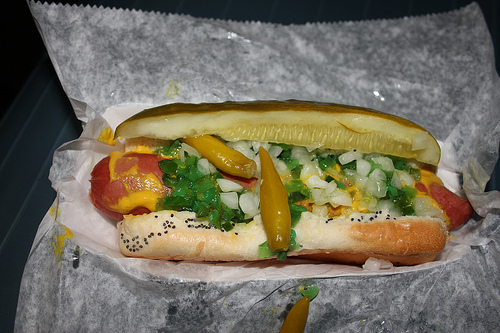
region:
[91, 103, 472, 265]
a hot dog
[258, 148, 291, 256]
small pickles in a hot dog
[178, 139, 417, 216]
chopped white onions in a hot dog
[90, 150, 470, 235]
a hot dog wiener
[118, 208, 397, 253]
poppy seeds on a hot dog bun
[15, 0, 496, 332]
a white paper wrapper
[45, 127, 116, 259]
mustard on a white paper wrapper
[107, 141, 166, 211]
mustard on the tip of a wiener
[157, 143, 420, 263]
relish on a hot dog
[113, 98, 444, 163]
a long slice of pickle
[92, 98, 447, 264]
A hotdog in the wrapper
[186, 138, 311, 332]
Peppers around the hotdog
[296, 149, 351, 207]
Onions on the hotdog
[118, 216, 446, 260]
A bun in the wrapper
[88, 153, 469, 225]
A hotdog between the buns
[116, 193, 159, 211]
Mustard on the hotdog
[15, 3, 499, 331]
A wrapper holding the hotdog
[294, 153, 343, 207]
The onions are white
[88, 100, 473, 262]
The hotdog is cooked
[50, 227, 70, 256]
Mustard sauce on the wrapper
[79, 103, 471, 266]
a hot dog sandwich with poppy seeds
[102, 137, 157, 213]
melted yellow cheese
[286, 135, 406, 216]
chopped onions over green scallions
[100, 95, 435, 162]
a spear of a garlic dill deli pickle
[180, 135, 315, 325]
pickled peppers over onions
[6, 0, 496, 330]
the white waxed paper that wrapped the hotdog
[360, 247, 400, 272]
bits of onion under the roll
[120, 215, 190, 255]
a cluster of poppy seeds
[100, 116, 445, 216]
golden mustard sticking out of roll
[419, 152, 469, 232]
end of the hotdog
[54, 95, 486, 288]
sausage inside of sausage bun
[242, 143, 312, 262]
yellow banana pepper on top of sausage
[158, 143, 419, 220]
green chopped vegetable on top of sausage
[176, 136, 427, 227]
chopped onion on top of sausage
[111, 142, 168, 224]
mustard on top of sausage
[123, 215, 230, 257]
black seeds on top of sausage bun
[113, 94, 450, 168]
long green sliced pickle on top of sausage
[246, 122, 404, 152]
long pale seeds in pickle on top of sausage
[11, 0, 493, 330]
white wax paper holding sausage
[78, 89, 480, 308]
white paper tray holding sausage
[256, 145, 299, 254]
pepper on top of hot dog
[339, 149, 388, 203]
onions on top of hot dog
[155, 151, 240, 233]
green relish on top of hot dog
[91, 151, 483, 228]
hot dog in bun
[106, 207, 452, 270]
poppy seeds on hot dog bun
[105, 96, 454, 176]
spear of a pickle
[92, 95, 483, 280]
hot dog with lots of condiments on it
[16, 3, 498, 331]
wax paper surrounding hot dog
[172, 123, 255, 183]
pepper on top of hot dog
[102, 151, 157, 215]
yellow mustard on hot dog